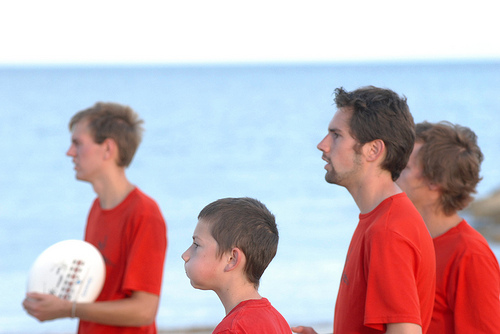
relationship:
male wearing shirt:
[24, 104, 167, 333] [77, 187, 168, 332]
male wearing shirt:
[181, 198, 291, 333] [211, 298, 292, 333]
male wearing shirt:
[318, 86, 438, 333] [333, 192, 437, 332]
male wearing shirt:
[394, 123, 499, 333] [427, 220, 500, 333]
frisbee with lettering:
[27, 239, 106, 304] [48, 258, 82, 301]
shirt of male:
[333, 192, 437, 332] [318, 86, 438, 333]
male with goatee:
[318, 86, 438, 333] [326, 169, 339, 184]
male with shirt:
[181, 198, 291, 333] [211, 298, 292, 333]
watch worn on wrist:
[70, 302, 77, 318] [67, 301, 86, 319]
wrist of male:
[67, 301, 86, 319] [24, 104, 167, 333]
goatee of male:
[326, 169, 339, 184] [318, 86, 438, 333]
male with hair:
[318, 86, 438, 333] [335, 87, 418, 183]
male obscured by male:
[394, 123, 499, 333] [318, 86, 438, 333]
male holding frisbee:
[24, 104, 167, 333] [27, 239, 106, 304]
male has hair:
[24, 104, 167, 333] [69, 104, 140, 168]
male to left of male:
[318, 86, 438, 333] [181, 198, 291, 333]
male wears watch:
[24, 104, 167, 333] [70, 302, 77, 318]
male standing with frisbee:
[24, 104, 167, 333] [27, 239, 106, 304]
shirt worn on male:
[77, 187, 168, 332] [24, 104, 167, 333]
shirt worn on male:
[211, 298, 292, 333] [181, 198, 291, 333]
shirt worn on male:
[427, 220, 500, 333] [394, 123, 499, 333]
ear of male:
[224, 247, 242, 272] [181, 198, 291, 333]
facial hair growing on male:
[321, 152, 363, 185] [318, 86, 438, 333]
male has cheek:
[181, 198, 291, 333] [186, 255, 216, 286]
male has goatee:
[318, 86, 438, 333] [326, 169, 339, 184]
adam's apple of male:
[93, 181, 104, 196] [24, 104, 167, 333]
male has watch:
[24, 104, 167, 333] [70, 302, 77, 318]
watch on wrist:
[70, 302, 77, 318] [67, 301, 86, 319]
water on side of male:
[1, 61, 498, 333] [24, 104, 167, 333]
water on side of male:
[1, 61, 498, 333] [181, 198, 291, 333]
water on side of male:
[1, 61, 498, 333] [318, 86, 438, 333]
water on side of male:
[1, 61, 498, 333] [394, 123, 499, 333]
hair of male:
[198, 198, 280, 289] [181, 198, 291, 333]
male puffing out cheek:
[181, 198, 291, 333] [186, 255, 216, 286]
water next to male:
[1, 61, 498, 333] [24, 104, 167, 333]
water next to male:
[1, 61, 498, 333] [181, 198, 291, 333]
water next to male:
[1, 61, 498, 333] [318, 86, 438, 333]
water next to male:
[1, 61, 498, 333] [394, 123, 499, 333]